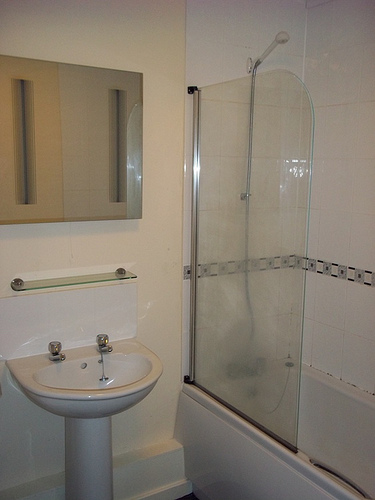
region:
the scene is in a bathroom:
[18, 20, 374, 498]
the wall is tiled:
[305, 43, 355, 114]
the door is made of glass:
[225, 82, 289, 453]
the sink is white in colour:
[64, 315, 126, 432]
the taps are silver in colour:
[27, 314, 121, 360]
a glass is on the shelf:
[6, 259, 132, 287]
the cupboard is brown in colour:
[5, 53, 145, 213]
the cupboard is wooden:
[0, 82, 145, 215]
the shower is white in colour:
[259, 26, 301, 67]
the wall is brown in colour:
[137, 239, 175, 325]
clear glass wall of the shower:
[189, 67, 310, 444]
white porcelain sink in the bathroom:
[20, 328, 155, 495]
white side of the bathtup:
[205, 438, 283, 498]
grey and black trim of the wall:
[311, 253, 366, 292]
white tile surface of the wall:
[313, 289, 367, 367]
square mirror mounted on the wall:
[0, 49, 162, 227]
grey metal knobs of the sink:
[44, 333, 113, 365]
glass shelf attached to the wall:
[1, 258, 142, 301]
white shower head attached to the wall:
[243, 24, 292, 73]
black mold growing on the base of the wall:
[312, 360, 371, 400]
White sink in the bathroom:
[12, 335, 167, 429]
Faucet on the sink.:
[36, 331, 125, 355]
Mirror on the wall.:
[29, 51, 143, 222]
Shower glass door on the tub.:
[214, 92, 314, 372]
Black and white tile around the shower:
[195, 261, 371, 279]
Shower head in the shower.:
[239, 22, 297, 74]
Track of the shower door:
[308, 457, 359, 495]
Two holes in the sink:
[76, 354, 104, 367]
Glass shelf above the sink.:
[13, 265, 135, 291]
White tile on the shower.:
[320, 84, 363, 237]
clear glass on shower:
[173, 81, 318, 460]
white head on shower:
[250, 14, 282, 74]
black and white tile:
[188, 250, 373, 316]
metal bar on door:
[178, 89, 223, 394]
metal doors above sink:
[0, 71, 135, 221]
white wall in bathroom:
[32, 226, 147, 259]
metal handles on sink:
[34, 335, 116, 357]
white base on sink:
[69, 419, 120, 499]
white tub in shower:
[223, 346, 373, 498]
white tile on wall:
[316, 61, 373, 174]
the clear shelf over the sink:
[6, 263, 139, 295]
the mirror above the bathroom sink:
[1, 50, 150, 233]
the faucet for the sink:
[97, 329, 115, 354]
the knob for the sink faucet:
[46, 337, 65, 352]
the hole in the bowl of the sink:
[78, 361, 88, 370]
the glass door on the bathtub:
[187, 68, 317, 436]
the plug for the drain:
[279, 358, 296, 367]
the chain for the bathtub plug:
[264, 367, 297, 420]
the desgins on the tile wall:
[318, 254, 373, 301]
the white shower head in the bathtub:
[256, 22, 292, 71]